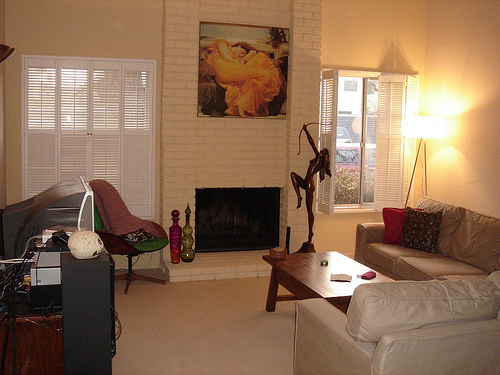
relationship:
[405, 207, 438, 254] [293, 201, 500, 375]
pillow on couch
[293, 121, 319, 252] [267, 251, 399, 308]
statue on table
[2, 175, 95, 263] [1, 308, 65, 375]
tv on shelf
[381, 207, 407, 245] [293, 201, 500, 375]
pillow on top of couch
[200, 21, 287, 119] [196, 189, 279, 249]
painting above fireplace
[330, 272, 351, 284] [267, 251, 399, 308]
paper on top of table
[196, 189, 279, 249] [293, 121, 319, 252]
fireplace next to statue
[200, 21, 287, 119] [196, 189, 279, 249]
painting hanging above fireplace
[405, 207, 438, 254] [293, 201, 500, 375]
pillow sitting on couch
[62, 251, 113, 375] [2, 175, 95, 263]
speaker next to tv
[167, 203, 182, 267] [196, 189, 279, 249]
bottle sitting in front of fireplace